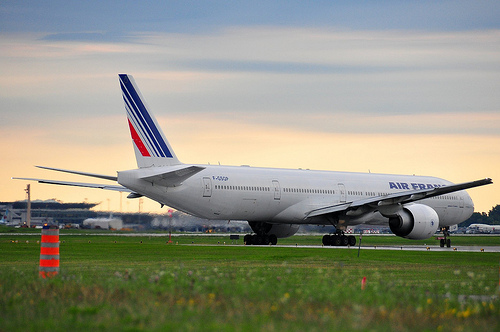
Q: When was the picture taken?
A: Daytime.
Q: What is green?
A: Grass.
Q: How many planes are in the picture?
A: One.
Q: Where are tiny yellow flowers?
A: In the grass.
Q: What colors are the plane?
A: White, blue and red.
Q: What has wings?
A: The airplane.